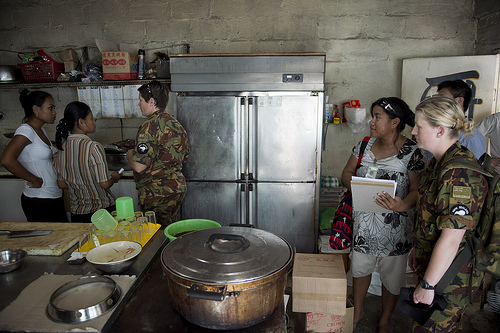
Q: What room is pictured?
A: It is a kitchen.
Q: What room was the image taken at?
A: It was taken at the kitchen.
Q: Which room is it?
A: It is a kitchen.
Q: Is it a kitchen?
A: Yes, it is a kitchen.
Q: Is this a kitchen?
A: Yes, it is a kitchen.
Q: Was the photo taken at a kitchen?
A: Yes, it was taken in a kitchen.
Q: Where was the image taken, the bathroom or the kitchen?
A: It was taken at the kitchen.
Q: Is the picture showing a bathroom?
A: No, the picture is showing a kitchen.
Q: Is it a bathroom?
A: No, it is a kitchen.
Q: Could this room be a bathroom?
A: No, it is a kitchen.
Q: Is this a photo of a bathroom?
A: No, the picture is showing a kitchen.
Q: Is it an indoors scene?
A: Yes, it is indoors.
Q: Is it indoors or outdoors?
A: It is indoors.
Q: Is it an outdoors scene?
A: No, it is indoors.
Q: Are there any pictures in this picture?
A: No, there are no pictures.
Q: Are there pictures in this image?
A: No, there are no pictures.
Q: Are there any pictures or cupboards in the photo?
A: No, there are no pictures or cupboards.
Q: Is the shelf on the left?
A: Yes, the shelf is on the left of the image.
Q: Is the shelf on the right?
A: No, the shelf is on the left of the image.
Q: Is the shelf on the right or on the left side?
A: The shelf is on the left of the image.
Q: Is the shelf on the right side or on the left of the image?
A: The shelf is on the left of the image.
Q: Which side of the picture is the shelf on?
A: The shelf is on the left of the image.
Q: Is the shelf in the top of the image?
A: Yes, the shelf is in the top of the image.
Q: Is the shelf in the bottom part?
A: No, the shelf is in the top of the image.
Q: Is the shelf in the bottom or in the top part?
A: The shelf is in the top of the image.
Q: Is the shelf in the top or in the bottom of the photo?
A: The shelf is in the top of the image.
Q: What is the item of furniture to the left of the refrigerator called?
A: The piece of furniture is a shelf.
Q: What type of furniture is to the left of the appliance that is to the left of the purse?
A: The piece of furniture is a shelf.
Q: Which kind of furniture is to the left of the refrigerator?
A: The piece of furniture is a shelf.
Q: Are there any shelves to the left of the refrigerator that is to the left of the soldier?
A: Yes, there is a shelf to the left of the freezer.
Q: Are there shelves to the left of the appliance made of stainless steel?
A: Yes, there is a shelf to the left of the freezer.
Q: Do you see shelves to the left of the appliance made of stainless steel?
A: Yes, there is a shelf to the left of the freezer.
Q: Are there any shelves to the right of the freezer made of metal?
A: No, the shelf is to the left of the refrigerator.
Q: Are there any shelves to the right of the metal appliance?
A: No, the shelf is to the left of the refrigerator.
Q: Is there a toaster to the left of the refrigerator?
A: No, there is a shelf to the left of the refrigerator.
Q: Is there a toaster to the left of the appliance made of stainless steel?
A: No, there is a shelf to the left of the refrigerator.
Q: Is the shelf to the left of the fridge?
A: Yes, the shelf is to the left of the fridge.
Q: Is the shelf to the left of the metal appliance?
A: Yes, the shelf is to the left of the fridge.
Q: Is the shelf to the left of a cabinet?
A: No, the shelf is to the left of the fridge.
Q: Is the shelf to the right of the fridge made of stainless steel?
A: No, the shelf is to the left of the freezer.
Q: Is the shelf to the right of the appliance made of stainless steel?
A: No, the shelf is to the left of the freezer.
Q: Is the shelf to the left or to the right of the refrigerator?
A: The shelf is to the left of the refrigerator.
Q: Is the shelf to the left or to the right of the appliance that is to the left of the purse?
A: The shelf is to the left of the refrigerator.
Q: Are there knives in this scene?
A: Yes, there is a knife.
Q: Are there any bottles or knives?
A: Yes, there is a knife.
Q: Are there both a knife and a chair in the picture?
A: No, there is a knife but no chairs.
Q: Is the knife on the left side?
A: Yes, the knife is on the left of the image.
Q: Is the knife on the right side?
A: No, the knife is on the left of the image.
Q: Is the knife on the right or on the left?
A: The knife is on the left of the image.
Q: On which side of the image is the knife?
A: The knife is on the left of the image.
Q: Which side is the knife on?
A: The knife is on the left of the image.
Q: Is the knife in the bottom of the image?
A: Yes, the knife is in the bottom of the image.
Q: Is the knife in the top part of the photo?
A: No, the knife is in the bottom of the image.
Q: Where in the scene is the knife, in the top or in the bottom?
A: The knife is in the bottom of the image.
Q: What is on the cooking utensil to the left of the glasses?
A: The knife is on the cutting board.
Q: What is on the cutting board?
A: The knife is on the cutting board.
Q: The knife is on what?
A: The knife is on the cutting board.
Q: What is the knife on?
A: The knife is on the cutting board.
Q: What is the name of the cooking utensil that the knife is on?
A: The cooking utensil is a cutting board.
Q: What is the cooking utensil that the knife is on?
A: The cooking utensil is a cutting board.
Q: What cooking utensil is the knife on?
A: The knife is on the cutting board.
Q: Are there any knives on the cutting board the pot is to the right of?
A: Yes, there is a knife on the cutting board.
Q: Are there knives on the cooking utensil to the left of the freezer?
A: Yes, there is a knife on the cutting board.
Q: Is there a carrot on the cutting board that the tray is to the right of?
A: No, there is a knife on the cutting board.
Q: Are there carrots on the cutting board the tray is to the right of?
A: No, there is a knife on the cutting board.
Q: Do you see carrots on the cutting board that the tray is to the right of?
A: No, there is a knife on the cutting board.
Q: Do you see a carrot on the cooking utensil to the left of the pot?
A: No, there is a knife on the cutting board.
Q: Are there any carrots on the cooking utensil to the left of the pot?
A: No, there is a knife on the cutting board.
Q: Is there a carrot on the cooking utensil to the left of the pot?
A: No, there is a knife on the cutting board.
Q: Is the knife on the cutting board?
A: Yes, the knife is on the cutting board.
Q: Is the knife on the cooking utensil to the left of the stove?
A: Yes, the knife is on the cutting board.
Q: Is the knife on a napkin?
A: No, the knife is on the cutting board.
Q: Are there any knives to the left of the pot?
A: Yes, there is a knife to the left of the pot.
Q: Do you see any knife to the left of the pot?
A: Yes, there is a knife to the left of the pot.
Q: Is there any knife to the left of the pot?
A: Yes, there is a knife to the left of the pot.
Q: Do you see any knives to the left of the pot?
A: Yes, there is a knife to the left of the pot.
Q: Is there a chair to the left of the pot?
A: No, there is a knife to the left of the pot.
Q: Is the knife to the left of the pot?
A: Yes, the knife is to the left of the pot.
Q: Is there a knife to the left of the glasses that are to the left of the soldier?
A: Yes, there is a knife to the left of the glasses.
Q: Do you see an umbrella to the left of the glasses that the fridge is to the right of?
A: No, there is a knife to the left of the glasses.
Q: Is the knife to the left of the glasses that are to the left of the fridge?
A: Yes, the knife is to the left of the glasses.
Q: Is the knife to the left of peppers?
A: No, the knife is to the left of the glasses.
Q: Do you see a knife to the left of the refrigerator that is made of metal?
A: Yes, there is a knife to the left of the freezer.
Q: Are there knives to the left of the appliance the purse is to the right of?
A: Yes, there is a knife to the left of the freezer.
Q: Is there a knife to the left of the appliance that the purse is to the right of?
A: Yes, there is a knife to the left of the freezer.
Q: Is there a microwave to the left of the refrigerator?
A: No, there is a knife to the left of the refrigerator.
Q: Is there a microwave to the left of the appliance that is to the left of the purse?
A: No, there is a knife to the left of the refrigerator.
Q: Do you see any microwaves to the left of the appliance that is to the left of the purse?
A: No, there is a knife to the left of the refrigerator.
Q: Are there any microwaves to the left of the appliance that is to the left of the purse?
A: No, there is a knife to the left of the refrigerator.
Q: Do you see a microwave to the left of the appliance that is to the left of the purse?
A: No, there is a knife to the left of the refrigerator.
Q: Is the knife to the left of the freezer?
A: Yes, the knife is to the left of the freezer.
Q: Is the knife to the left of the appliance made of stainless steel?
A: Yes, the knife is to the left of the freezer.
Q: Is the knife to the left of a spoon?
A: No, the knife is to the left of the freezer.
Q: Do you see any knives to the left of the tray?
A: Yes, there is a knife to the left of the tray.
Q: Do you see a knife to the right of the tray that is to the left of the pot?
A: No, the knife is to the left of the tray.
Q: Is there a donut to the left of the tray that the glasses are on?
A: No, there is a knife to the left of the tray.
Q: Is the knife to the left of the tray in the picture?
A: Yes, the knife is to the left of the tray.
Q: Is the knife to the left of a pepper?
A: No, the knife is to the left of the tray.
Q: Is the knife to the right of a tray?
A: No, the knife is to the left of a tray.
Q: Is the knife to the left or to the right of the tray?
A: The knife is to the left of the tray.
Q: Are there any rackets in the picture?
A: No, there are no rackets.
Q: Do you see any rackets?
A: No, there are no rackets.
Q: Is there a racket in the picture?
A: No, there are no rackets.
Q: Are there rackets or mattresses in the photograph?
A: No, there are no rackets or mattresses.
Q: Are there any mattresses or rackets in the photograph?
A: No, there are no rackets or mattresses.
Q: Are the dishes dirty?
A: Yes, the dishes are dirty.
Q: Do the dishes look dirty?
A: Yes, the dishes are dirty.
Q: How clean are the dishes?
A: The dishes are dirty.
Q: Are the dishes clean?
A: No, the dishes are dirty.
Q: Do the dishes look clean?
A: No, the dishes are dirty.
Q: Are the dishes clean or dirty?
A: The dishes are dirty.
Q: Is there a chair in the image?
A: No, there are no chairs.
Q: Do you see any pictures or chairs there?
A: No, there are no chairs or pictures.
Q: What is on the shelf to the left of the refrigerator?
A: The box is on the shelf.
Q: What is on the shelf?
A: The box is on the shelf.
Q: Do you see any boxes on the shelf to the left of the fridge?
A: Yes, there is a box on the shelf.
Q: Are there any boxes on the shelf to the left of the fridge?
A: Yes, there is a box on the shelf.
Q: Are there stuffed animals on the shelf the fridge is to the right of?
A: No, there is a box on the shelf.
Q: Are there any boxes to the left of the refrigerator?
A: Yes, there is a box to the left of the refrigerator.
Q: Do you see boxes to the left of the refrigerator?
A: Yes, there is a box to the left of the refrigerator.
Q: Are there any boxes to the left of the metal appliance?
A: Yes, there is a box to the left of the refrigerator.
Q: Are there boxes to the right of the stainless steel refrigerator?
A: No, the box is to the left of the fridge.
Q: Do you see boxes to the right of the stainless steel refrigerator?
A: No, the box is to the left of the fridge.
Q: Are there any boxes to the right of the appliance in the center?
A: No, the box is to the left of the fridge.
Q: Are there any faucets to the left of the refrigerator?
A: No, there is a box to the left of the refrigerator.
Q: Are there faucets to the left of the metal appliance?
A: No, there is a box to the left of the refrigerator.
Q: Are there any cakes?
A: No, there are no cakes.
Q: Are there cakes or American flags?
A: No, there are no cakes or American flags.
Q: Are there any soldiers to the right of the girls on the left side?
A: Yes, there is a soldier to the right of the girls.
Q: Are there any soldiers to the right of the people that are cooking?
A: Yes, there is a soldier to the right of the girls.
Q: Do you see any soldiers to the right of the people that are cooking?
A: Yes, there is a soldier to the right of the girls.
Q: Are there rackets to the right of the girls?
A: No, there is a soldier to the right of the girls.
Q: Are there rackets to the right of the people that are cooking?
A: No, there is a soldier to the right of the girls.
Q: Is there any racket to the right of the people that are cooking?
A: No, there is a soldier to the right of the girls.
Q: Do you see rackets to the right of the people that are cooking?
A: No, there is a soldier to the right of the girls.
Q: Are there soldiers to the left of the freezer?
A: Yes, there is a soldier to the left of the freezer.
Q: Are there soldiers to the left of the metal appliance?
A: Yes, there is a soldier to the left of the freezer.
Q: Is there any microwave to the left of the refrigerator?
A: No, there is a soldier to the left of the refrigerator.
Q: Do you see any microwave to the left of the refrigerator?
A: No, there is a soldier to the left of the refrigerator.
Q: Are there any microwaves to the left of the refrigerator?
A: No, there is a soldier to the left of the refrigerator.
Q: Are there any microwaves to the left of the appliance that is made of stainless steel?
A: No, there is a soldier to the left of the refrigerator.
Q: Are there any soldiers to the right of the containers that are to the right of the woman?
A: Yes, there is a soldier to the right of the containers.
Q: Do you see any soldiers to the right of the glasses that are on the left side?
A: Yes, there is a soldier to the right of the glasses.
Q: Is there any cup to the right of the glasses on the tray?
A: No, there is a soldier to the right of the glasses.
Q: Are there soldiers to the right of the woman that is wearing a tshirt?
A: Yes, there is a soldier to the right of the woman.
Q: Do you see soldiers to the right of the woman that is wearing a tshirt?
A: Yes, there is a soldier to the right of the woman.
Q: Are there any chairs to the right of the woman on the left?
A: No, there is a soldier to the right of the woman.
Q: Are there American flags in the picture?
A: No, there are no American flags.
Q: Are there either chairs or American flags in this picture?
A: No, there are no American flags or chairs.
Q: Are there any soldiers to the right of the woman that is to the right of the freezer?
A: Yes, there is a soldier to the right of the woman.